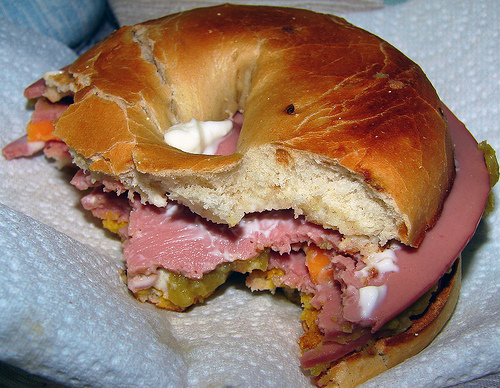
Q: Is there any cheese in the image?
A: Yes, there is cheese.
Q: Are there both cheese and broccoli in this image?
A: No, there is cheese but no broccoli.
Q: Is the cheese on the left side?
A: Yes, the cheese is on the left of the image.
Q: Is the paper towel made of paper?
A: Yes, the paper towel is made of paper.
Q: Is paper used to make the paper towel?
A: Yes, the paper towel is made of paper.